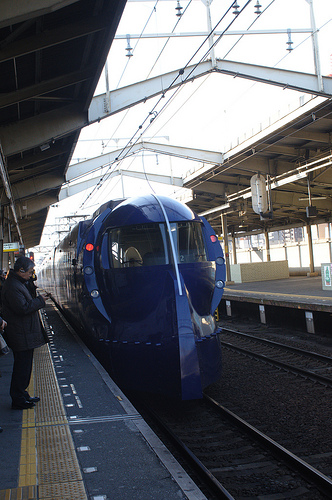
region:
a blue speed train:
[61, 185, 224, 392]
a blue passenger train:
[63, 193, 249, 385]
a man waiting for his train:
[0, 252, 55, 414]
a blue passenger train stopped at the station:
[57, 177, 262, 436]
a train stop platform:
[2, 6, 312, 455]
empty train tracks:
[231, 325, 326, 381]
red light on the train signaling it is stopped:
[78, 236, 99, 259]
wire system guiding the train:
[104, 8, 287, 155]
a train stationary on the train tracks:
[68, 190, 264, 498]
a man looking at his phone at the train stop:
[0, 247, 62, 489]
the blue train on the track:
[32, 193, 221, 399]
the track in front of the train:
[162, 396, 328, 497]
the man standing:
[4, 255, 50, 411]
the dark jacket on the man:
[4, 266, 48, 349]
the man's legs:
[10, 350, 38, 410]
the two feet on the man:
[13, 394, 41, 407]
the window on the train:
[102, 221, 213, 267]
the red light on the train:
[85, 244, 92, 250]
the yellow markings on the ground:
[5, 322, 89, 498]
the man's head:
[12, 254, 34, 280]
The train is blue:
[26, 191, 224, 402]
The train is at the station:
[38, 188, 235, 393]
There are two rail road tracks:
[142, 312, 326, 478]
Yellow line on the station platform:
[17, 318, 92, 492]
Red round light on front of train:
[82, 240, 96, 253]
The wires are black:
[55, 3, 268, 230]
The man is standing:
[5, 256, 51, 409]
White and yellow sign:
[3, 238, 24, 256]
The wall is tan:
[228, 252, 297, 285]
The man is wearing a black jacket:
[4, 256, 60, 361]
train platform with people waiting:
[1, 279, 198, 498]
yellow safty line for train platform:
[22, 285, 88, 498]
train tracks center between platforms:
[141, 309, 329, 497]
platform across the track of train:
[186, 127, 331, 335]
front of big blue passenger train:
[48, 196, 231, 398]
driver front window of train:
[104, 220, 207, 264]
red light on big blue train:
[86, 244, 93, 250]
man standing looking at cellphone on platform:
[2, 258, 52, 410]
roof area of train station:
[2, 0, 331, 203]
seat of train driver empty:
[121, 247, 144, 266]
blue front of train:
[84, 193, 232, 388]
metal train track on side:
[277, 344, 321, 390]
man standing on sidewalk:
[5, 252, 45, 390]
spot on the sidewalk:
[83, 460, 100, 475]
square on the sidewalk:
[76, 440, 92, 452]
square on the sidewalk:
[72, 426, 86, 438]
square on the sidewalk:
[66, 399, 76, 407]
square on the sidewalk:
[63, 391, 70, 400]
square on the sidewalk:
[80, 461, 98, 479]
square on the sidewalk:
[83, 464, 103, 482]